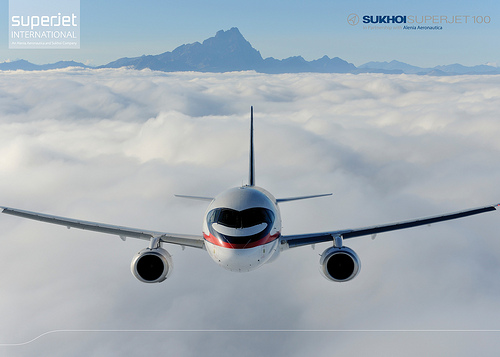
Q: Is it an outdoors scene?
A: Yes, it is outdoors.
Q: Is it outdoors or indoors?
A: It is outdoors.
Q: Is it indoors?
A: No, it is outdoors.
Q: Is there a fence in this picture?
A: No, there are no fences.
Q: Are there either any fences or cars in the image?
A: No, there are no fences or cars.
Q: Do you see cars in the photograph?
A: No, there are no cars.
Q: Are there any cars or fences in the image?
A: No, there are no cars or fences.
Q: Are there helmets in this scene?
A: No, there are no helmets.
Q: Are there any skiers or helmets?
A: No, there are no helmets or skiers.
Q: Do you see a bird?
A: No, there are no birds.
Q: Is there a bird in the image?
A: No, there are no birds.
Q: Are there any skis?
A: No, there are no skis.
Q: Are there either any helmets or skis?
A: No, there are no skis or helmets.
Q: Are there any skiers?
A: No, there are no skiers.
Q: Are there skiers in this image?
A: No, there are no skiers.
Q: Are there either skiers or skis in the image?
A: No, there are no skiers or skis.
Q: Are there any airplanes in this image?
A: Yes, there is an airplane.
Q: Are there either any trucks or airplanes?
A: Yes, there is an airplane.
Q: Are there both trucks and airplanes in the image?
A: No, there is an airplane but no trucks.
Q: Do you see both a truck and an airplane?
A: No, there is an airplane but no trucks.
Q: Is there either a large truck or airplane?
A: Yes, there is a large airplane.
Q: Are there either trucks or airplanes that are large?
A: Yes, the airplane is large.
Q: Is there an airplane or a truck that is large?
A: Yes, the airplane is large.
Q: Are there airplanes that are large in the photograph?
A: Yes, there is a large airplane.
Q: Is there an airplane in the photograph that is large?
A: Yes, there is an airplane that is large.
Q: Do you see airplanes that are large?
A: Yes, there is an airplane that is large.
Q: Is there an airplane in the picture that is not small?
A: Yes, there is a large airplane.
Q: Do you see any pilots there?
A: No, there are no pilots.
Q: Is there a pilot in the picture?
A: No, there are no pilots.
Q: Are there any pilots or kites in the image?
A: No, there are no pilots or kites.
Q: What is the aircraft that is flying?
A: The aircraft is an airplane.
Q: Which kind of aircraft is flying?
A: The aircraft is an airplane.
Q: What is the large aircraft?
A: The aircraft is an airplane.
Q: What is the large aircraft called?
A: The aircraft is an airplane.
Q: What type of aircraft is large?
A: The aircraft is an airplane.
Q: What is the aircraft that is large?
A: The aircraft is an airplane.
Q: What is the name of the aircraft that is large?
A: The aircraft is an airplane.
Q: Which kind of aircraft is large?
A: The aircraft is an airplane.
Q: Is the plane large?
A: Yes, the plane is large.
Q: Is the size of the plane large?
A: Yes, the plane is large.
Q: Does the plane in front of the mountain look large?
A: Yes, the plane is large.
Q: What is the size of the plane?
A: The plane is large.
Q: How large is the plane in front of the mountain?
A: The plane is large.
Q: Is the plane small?
A: No, the plane is large.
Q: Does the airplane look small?
A: No, the airplane is large.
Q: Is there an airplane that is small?
A: No, there is an airplane but it is large.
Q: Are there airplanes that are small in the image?
A: No, there is an airplane but it is large.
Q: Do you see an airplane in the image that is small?
A: No, there is an airplane but it is large.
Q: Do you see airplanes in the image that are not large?
A: No, there is an airplane but it is large.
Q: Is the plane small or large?
A: The plane is large.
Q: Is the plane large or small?
A: The plane is large.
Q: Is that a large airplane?
A: Yes, that is a large airplane.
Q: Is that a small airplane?
A: No, that is a large airplane.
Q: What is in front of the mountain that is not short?
A: The airplane is in front of the mountain.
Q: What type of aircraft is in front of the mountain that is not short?
A: The aircraft is an airplane.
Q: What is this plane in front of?
A: The plane is in front of the mountain.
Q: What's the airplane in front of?
A: The plane is in front of the mountain.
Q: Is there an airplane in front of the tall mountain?
A: Yes, there is an airplane in front of the mountain.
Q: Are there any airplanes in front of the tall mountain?
A: Yes, there is an airplane in front of the mountain.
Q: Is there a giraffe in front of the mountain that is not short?
A: No, there is an airplane in front of the mountain.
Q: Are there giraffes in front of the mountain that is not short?
A: No, there is an airplane in front of the mountain.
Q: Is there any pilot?
A: No, there are no pilots.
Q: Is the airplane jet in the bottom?
A: Yes, the jet is in the bottom of the image.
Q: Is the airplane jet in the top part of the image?
A: No, the jet is in the bottom of the image.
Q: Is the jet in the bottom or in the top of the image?
A: The jet is in the bottom of the image.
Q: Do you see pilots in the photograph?
A: No, there are no pilots.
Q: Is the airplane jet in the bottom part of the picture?
A: Yes, the jet is in the bottom of the image.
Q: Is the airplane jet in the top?
A: No, the jet is in the bottom of the image.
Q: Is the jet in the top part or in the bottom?
A: The jet is in the bottom of the image.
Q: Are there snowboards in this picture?
A: No, there are no snowboards.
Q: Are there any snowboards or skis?
A: No, there are no snowboards or skis.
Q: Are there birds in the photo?
A: No, there are no birds.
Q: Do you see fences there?
A: No, there are no fences.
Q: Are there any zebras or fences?
A: No, there are no fences or zebras.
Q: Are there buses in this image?
A: No, there are no buses.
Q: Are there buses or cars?
A: No, there are no buses or cars.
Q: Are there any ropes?
A: No, there are no ropes.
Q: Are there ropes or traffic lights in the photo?
A: No, there are no ropes or traffic lights.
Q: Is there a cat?
A: No, there are no cats.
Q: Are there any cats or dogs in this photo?
A: No, there are no cats or dogs.